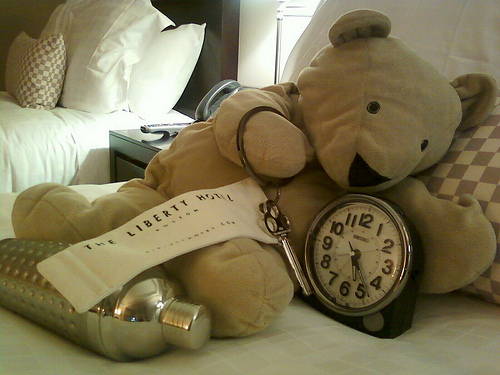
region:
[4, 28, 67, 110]
Checkered pillow leaning on white pillow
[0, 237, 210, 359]
Cocktail shaker on teddy bear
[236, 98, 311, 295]
Key around teddy bear's wrist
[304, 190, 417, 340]
Clock on teddy bear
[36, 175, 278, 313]
White napkin on teddy bear and cocktail shaker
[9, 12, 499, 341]
Large teddy bear on bed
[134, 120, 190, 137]
TV remote on nighstand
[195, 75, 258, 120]
Bed behind television remote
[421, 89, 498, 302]
Checkered pillow behind teddy bear leaning on white pillow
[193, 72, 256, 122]
Telephone next to bed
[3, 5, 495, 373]
Picture of a hotel bedroom.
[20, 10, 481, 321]
A small stuffed bear lying on a bed.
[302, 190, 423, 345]
Old clock next to the bear.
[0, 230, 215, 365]
A silver bottle of liqueur on the bed.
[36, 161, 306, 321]
Hotel room key on the bear's right hand.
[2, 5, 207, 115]
Standing pillows on the bed.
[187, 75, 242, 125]
The phone is on the nightstand.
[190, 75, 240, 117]
The telephone is grey.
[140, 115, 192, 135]
The TV remote control is next to the telephone.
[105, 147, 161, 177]
Nightstand with a drawer.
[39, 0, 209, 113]
white pillows on a bed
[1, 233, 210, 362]
a metal bottle on a bed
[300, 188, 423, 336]
a black alarm clock on a bed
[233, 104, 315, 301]
a teddy bear holding a key ring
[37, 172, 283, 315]
a white small banner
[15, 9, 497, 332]
a brown teddy bear laying its head on a pillow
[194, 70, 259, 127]
a lack landline phone on a table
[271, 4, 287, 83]
metal stand of a lamp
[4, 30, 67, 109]
a checkered white and brown pillow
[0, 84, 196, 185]
a bed with white bedding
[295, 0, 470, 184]
Head of a ted bear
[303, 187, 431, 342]
This is a clock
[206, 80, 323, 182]
Hand of a ted bear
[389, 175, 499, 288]
Hand of a ted bear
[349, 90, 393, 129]
Eye of a ted bear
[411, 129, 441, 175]
Eye of a ted bear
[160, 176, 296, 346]
Leg of a ted bear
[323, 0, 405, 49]
Ear of a ted bear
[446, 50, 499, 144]
Ear of a ted bear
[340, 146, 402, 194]
Mouth of a ted bear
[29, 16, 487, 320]
reclined stuffed teddy bear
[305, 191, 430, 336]
clock in front of bear arm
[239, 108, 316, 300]
silver key on handle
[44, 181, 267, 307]
label with black words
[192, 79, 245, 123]
silver handset of phone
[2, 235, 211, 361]
silver flask laying horizontally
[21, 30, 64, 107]
decorative pillow on bed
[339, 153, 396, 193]
black nose on face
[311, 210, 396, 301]
black numbers on clock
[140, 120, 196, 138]
remote control on table